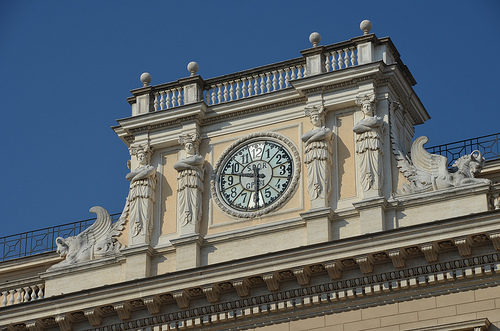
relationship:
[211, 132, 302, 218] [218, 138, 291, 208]
clock has face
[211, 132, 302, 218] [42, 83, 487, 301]
clock on wall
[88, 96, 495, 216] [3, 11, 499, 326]
statues on building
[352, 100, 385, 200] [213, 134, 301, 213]
statue next to clock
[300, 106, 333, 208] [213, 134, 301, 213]
statues next to clock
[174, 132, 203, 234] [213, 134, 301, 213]
statues next to clock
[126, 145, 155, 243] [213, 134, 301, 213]
statues next to clock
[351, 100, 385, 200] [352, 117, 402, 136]
statue crossed arms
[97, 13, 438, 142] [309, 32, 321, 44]
ledge has globe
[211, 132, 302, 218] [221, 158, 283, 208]
clock reads 9:30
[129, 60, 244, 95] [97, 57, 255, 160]
globes on left side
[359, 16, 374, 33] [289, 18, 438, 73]
globe on right side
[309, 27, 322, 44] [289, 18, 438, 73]
globe on right side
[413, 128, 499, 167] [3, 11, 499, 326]
railing in back of building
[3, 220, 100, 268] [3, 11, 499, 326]
railing in back of building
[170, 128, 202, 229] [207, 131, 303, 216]
statues standing next to clock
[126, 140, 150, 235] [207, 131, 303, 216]
statues standing next to clock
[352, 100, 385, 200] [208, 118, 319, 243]
statue standing next to clock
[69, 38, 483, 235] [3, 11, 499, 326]
top of a building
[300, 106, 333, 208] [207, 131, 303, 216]
statues on both sides of clock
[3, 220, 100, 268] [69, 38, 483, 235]
railing on top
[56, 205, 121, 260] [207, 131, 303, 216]
statue facing away clock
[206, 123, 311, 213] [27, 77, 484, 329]
clock on building